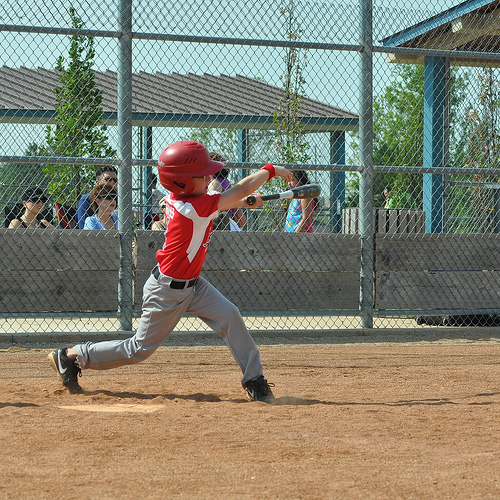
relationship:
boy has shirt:
[50, 141, 295, 404] [156, 193, 222, 280]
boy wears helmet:
[50, 141, 295, 404] [157, 142, 227, 195]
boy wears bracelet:
[50, 141, 295, 404] [259, 162, 277, 180]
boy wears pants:
[50, 141, 295, 404] [73, 263, 264, 386]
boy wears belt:
[50, 141, 295, 404] [151, 263, 200, 290]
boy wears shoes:
[50, 141, 295, 404] [46, 347, 278, 405]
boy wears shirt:
[50, 141, 295, 404] [156, 193, 222, 280]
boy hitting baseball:
[50, 141, 295, 404] [245, 178, 328, 212]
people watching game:
[7, 154, 317, 229] [7, 145, 496, 452]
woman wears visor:
[9, 186, 57, 230] [20, 187, 49, 203]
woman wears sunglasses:
[9, 186, 57, 230] [24, 196, 47, 205]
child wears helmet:
[50, 141, 295, 404] [157, 142, 227, 195]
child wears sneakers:
[50, 141, 295, 404] [46, 347, 278, 405]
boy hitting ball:
[50, 141, 295, 404] [245, 178, 328, 212]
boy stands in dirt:
[50, 141, 295, 404] [57, 345, 489, 490]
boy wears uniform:
[50, 141, 295, 404] [80, 193, 264, 381]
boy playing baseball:
[50, 141, 295, 404] [245, 178, 328, 212]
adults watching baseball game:
[7, 154, 317, 229] [7, 145, 496, 452]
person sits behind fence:
[83, 184, 119, 229] [1, 4, 499, 333]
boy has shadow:
[50, 141, 295, 404] [71, 385, 499, 406]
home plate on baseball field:
[54, 401, 169, 415] [0, 334, 489, 498]